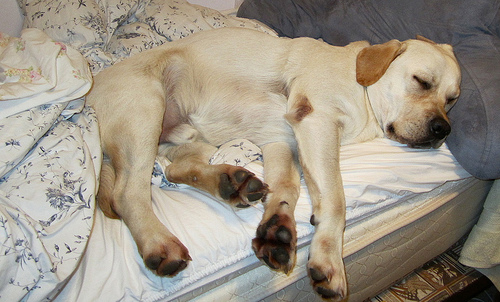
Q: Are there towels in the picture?
A: Yes, there is a towel.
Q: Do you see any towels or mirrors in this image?
A: Yes, there is a towel.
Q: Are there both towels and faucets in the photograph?
A: No, there is a towel but no faucets.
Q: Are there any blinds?
A: No, there are no blinds.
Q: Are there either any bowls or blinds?
A: No, there are no blinds or bowls.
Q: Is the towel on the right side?
A: Yes, the towel is on the right of the image.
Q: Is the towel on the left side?
A: No, the towel is on the right of the image.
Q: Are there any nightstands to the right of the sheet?
A: No, there is a towel to the right of the sheet.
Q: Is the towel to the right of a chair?
A: No, the towel is to the right of the bed sheet.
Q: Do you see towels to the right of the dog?
A: Yes, there is a towel to the right of the dog.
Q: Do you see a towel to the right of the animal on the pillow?
A: Yes, there is a towel to the right of the dog.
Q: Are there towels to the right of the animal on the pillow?
A: Yes, there is a towel to the right of the dog.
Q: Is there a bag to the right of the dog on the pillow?
A: No, there is a towel to the right of the dog.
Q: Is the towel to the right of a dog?
A: Yes, the towel is to the right of a dog.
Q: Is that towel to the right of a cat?
A: No, the towel is to the right of a dog.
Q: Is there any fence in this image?
A: No, there are no fences.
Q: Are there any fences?
A: No, there are no fences.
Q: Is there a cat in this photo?
A: No, there are no cats.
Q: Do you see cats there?
A: No, there are no cats.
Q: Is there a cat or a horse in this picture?
A: No, there are no cats or horses.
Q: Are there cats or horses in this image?
A: No, there are no cats or horses.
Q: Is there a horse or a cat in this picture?
A: No, there are no cats or horses.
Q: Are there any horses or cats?
A: No, there are no cats or horses.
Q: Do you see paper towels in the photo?
A: No, there are no paper towels.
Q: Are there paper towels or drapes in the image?
A: No, there are no paper towels or drapes.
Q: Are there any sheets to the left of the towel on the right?
A: Yes, there is a sheet to the left of the towel.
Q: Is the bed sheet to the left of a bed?
A: No, the bed sheet is to the left of the towel.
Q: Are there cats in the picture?
A: No, there are no cats.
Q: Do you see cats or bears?
A: No, there are no cats or bears.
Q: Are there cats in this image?
A: No, there are no cats.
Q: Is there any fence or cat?
A: No, there are no cats or fences.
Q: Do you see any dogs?
A: Yes, there is a dog.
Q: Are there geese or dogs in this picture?
A: Yes, there is a dog.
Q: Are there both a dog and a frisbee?
A: No, there is a dog but no frisbees.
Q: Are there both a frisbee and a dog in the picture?
A: No, there is a dog but no frisbees.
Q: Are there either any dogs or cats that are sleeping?
A: Yes, the dog is sleeping.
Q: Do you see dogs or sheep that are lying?
A: Yes, the dog is lying.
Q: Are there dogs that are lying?
A: Yes, there is a dog that is lying.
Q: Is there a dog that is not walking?
A: Yes, there is a dog that is lying.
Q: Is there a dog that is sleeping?
A: Yes, there is a dog that is sleeping.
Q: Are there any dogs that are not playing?
A: Yes, there is a dog that is sleeping.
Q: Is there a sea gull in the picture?
A: No, there are no seagulls.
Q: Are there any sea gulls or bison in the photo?
A: No, there are no sea gulls or bison.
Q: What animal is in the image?
A: The animal is a dog.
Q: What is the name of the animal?
A: The animal is a dog.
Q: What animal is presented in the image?
A: The animal is a dog.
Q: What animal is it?
A: The animal is a dog.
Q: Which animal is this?
A: This is a dog.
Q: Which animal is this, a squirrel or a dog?
A: This is a dog.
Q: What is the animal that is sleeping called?
A: The animal is a dog.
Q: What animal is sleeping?
A: The animal is a dog.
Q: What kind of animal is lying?
A: The animal is a dog.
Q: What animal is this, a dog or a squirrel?
A: This is a dog.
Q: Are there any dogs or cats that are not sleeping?
A: No, there is a dog but it is sleeping.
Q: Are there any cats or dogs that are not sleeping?
A: No, there is a dog but it is sleeping.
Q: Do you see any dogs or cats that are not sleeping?
A: No, there is a dog but it is sleeping.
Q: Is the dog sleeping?
A: Yes, the dog is sleeping.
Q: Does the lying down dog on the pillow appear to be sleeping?
A: Yes, the dog is sleeping.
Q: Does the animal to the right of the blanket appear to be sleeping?
A: Yes, the dog is sleeping.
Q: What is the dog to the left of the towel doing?
A: The dog is sleeping.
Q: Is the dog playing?
A: No, the dog is sleeping.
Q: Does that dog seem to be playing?
A: No, the dog is sleeping.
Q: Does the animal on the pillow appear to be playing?
A: No, the dog is sleeping.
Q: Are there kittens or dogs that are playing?
A: No, there is a dog but it is sleeping.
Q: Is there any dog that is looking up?
A: No, there is a dog but it is sleeping.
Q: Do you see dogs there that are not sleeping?
A: No, there is a dog but it is sleeping.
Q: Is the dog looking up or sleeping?
A: The dog is sleeping.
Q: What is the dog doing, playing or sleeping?
A: The dog is sleeping.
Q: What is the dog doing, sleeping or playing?
A: The dog is sleeping.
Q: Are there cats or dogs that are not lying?
A: No, there is a dog but it is lying.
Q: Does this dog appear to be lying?
A: Yes, the dog is lying.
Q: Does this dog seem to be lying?
A: Yes, the dog is lying.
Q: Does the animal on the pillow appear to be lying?
A: Yes, the dog is lying.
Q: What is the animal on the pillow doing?
A: The dog is lying.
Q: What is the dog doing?
A: The dog is lying.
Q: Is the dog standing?
A: No, the dog is lying.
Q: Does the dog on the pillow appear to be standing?
A: No, the dog is lying.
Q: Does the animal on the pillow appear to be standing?
A: No, the dog is lying.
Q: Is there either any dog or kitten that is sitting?
A: No, there is a dog but it is lying.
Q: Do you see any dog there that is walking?
A: No, there is a dog but it is lying.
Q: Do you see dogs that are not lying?
A: No, there is a dog but it is lying.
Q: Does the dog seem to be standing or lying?
A: The dog is lying.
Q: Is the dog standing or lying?
A: The dog is lying.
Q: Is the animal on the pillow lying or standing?
A: The dog is lying.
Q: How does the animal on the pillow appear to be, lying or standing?
A: The dog is lying.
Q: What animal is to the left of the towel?
A: The animal is a dog.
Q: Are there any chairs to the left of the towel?
A: No, there is a dog to the left of the towel.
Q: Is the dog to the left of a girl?
A: No, the dog is to the left of the towel.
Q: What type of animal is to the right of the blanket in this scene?
A: The animal is a dog.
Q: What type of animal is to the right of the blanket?
A: The animal is a dog.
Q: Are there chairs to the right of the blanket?
A: No, there is a dog to the right of the blanket.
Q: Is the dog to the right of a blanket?
A: Yes, the dog is to the right of a blanket.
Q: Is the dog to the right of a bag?
A: No, the dog is to the right of a blanket.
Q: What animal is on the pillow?
A: The dog is on the pillow.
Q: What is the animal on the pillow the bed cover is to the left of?
A: The animal is a dog.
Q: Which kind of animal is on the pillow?
A: The animal is a dog.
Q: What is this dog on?
A: The dog is on the pillow.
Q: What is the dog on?
A: The dog is on the pillow.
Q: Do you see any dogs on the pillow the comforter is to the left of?
A: Yes, there is a dog on the pillow.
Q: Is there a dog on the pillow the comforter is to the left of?
A: Yes, there is a dog on the pillow.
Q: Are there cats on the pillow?
A: No, there is a dog on the pillow.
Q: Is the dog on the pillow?
A: Yes, the dog is on the pillow.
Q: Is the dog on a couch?
A: No, the dog is on the pillow.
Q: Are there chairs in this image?
A: No, there are no chairs.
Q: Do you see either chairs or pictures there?
A: No, there are no chairs or pictures.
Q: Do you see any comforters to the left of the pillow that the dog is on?
A: Yes, there is a comforter to the left of the pillow.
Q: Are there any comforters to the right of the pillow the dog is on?
A: No, the comforter is to the left of the pillow.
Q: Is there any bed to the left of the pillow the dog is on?
A: No, there is a comforter to the left of the pillow.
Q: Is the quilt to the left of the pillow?
A: Yes, the quilt is to the left of the pillow.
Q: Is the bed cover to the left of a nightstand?
A: No, the bed cover is to the left of the pillow.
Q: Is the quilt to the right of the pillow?
A: No, the quilt is to the left of the pillow.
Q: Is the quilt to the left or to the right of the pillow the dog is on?
A: The quilt is to the left of the pillow.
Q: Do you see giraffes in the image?
A: No, there are no giraffes.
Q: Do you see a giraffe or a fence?
A: No, there are no giraffes or fences.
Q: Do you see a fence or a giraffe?
A: No, there are no giraffes or fences.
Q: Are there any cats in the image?
A: No, there are no cats.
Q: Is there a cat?
A: No, there are no cats.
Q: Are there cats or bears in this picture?
A: No, there are no cats or bears.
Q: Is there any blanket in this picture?
A: Yes, there is a blanket.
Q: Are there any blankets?
A: Yes, there is a blanket.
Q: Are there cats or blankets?
A: Yes, there is a blanket.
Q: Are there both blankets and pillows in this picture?
A: Yes, there are both a blanket and a pillow.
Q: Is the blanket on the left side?
A: Yes, the blanket is on the left of the image.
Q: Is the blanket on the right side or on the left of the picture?
A: The blanket is on the left of the image.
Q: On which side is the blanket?
A: The blanket is on the left of the image.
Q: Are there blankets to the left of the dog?
A: Yes, there is a blanket to the left of the dog.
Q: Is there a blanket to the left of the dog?
A: Yes, there is a blanket to the left of the dog.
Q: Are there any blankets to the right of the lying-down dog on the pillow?
A: No, the blanket is to the left of the dog.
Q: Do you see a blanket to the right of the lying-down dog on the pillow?
A: No, the blanket is to the left of the dog.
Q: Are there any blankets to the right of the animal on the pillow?
A: No, the blanket is to the left of the dog.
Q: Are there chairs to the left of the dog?
A: No, there is a blanket to the left of the dog.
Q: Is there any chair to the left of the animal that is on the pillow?
A: No, there is a blanket to the left of the dog.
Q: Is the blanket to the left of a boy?
A: No, the blanket is to the left of a dog.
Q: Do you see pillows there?
A: Yes, there is a pillow.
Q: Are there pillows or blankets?
A: Yes, there is a pillow.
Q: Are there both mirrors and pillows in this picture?
A: No, there is a pillow but no mirrors.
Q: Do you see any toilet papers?
A: No, there are no toilet papers.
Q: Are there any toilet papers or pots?
A: No, there are no toilet papers or pots.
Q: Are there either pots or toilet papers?
A: No, there are no toilet papers or pots.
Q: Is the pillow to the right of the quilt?
A: Yes, the pillow is to the right of the quilt.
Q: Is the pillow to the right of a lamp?
A: No, the pillow is to the right of the quilt.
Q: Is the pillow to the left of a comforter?
A: No, the pillow is to the right of a comforter.